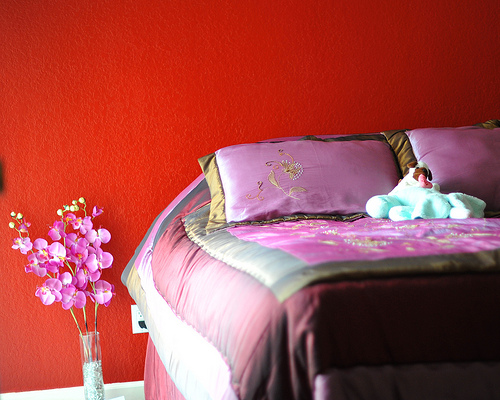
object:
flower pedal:
[34, 286, 49, 298]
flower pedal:
[58, 285, 77, 305]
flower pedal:
[72, 290, 86, 310]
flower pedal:
[58, 270, 75, 287]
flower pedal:
[47, 241, 67, 261]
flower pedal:
[78, 216, 92, 235]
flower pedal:
[96, 251, 113, 269]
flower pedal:
[94, 280, 111, 295]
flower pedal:
[46, 227, 62, 243]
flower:
[10, 234, 33, 254]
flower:
[56, 280, 87, 310]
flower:
[88, 276, 116, 306]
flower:
[80, 247, 113, 272]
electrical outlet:
[129, 301, 150, 334]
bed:
[120, 116, 499, 398]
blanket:
[119, 170, 499, 396]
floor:
[102, 385, 145, 398]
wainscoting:
[0, 378, 143, 398]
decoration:
[245, 145, 307, 203]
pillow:
[195, 130, 400, 234]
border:
[195, 131, 389, 232]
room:
[1, 0, 484, 395]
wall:
[1, 1, 187, 90]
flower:
[45, 220, 67, 242]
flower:
[69, 212, 93, 235]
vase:
[78, 329, 105, 399]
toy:
[366, 164, 486, 222]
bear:
[367, 160, 488, 219]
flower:
[31, 279, 68, 307]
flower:
[69, 248, 98, 286]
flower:
[87, 226, 110, 252]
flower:
[32, 237, 50, 256]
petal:
[98, 226, 110, 244]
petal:
[84, 229, 97, 244]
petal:
[79, 217, 92, 235]